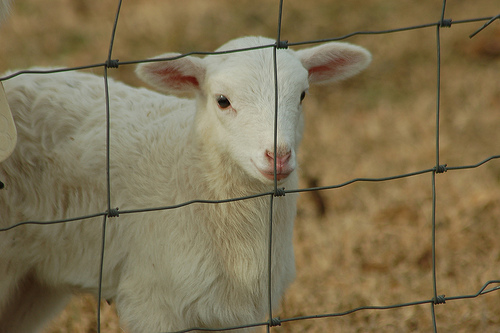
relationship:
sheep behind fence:
[0, 33, 375, 333] [90, 44, 480, 226]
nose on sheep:
[261, 145, 293, 170] [0, 33, 375, 333]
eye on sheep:
[210, 84, 244, 115] [0, 33, 375, 333]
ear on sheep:
[163, 70, 205, 89] [0, 33, 375, 333]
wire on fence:
[91, 30, 462, 75] [90, 44, 480, 226]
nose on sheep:
[261, 145, 293, 170] [12, 45, 354, 220]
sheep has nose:
[12, 45, 354, 220] [261, 145, 293, 170]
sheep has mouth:
[12, 45, 354, 220] [248, 165, 302, 188]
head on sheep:
[182, 41, 318, 178] [12, 45, 354, 220]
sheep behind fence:
[12, 45, 354, 220] [90, 44, 480, 226]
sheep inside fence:
[12, 45, 354, 220] [90, 44, 480, 226]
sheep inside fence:
[12, 45, 354, 220] [0, 0, 500, 333]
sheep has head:
[0, 33, 375, 333] [182, 41, 318, 178]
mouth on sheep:
[248, 165, 302, 188] [0, 33, 375, 333]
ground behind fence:
[310, 225, 476, 332] [90, 44, 480, 226]